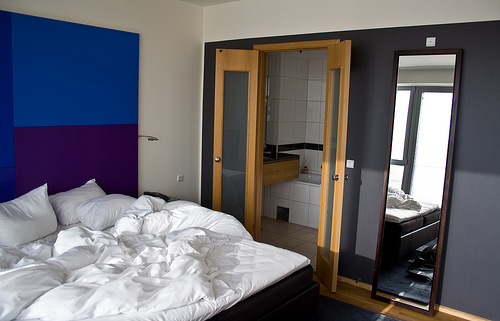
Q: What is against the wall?
A: A mirror.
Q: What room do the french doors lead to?
A: The bathroom.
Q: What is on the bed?
A: Pillows.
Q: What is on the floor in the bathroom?
A: Tiles.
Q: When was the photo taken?
A: During the daytime.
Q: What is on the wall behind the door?
A: The light switch.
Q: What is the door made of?
A: Glass and wood.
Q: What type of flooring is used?
A: Wood.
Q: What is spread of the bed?
A: Comforter.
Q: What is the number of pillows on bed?
A: Three.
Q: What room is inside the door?
A: Bathroom.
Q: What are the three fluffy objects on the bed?
A: Pillows.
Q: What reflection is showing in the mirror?
A: Bed.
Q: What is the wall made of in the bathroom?
A: Tiles.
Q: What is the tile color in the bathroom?
A: White and black.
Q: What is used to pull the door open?
A: Knob.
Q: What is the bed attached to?
A: Wall.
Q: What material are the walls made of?
A: Tile.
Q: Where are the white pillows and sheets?
A: On the bed.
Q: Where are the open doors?
A: Bathroom entrance.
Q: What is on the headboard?
A: Purple square.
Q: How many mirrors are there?
A: One.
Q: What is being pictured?
A: Bedroom and bathroom.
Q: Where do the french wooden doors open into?
A: Bathroom.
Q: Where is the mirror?
A: Resting against the wall.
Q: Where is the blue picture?
A: Head of the bed.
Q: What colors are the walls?
A: Gray and white.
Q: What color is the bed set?
A: White.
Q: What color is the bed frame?
A: Black.